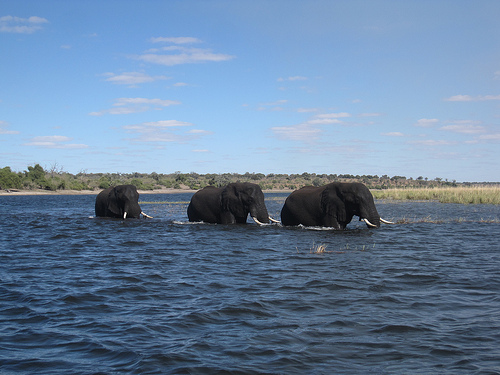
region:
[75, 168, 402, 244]
three elephants in the water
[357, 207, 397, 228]
elephant has two tusks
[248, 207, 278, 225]
elephant has two tusks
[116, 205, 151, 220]
elephant has two tusks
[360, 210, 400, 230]
tusks are color white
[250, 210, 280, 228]
tusks are color white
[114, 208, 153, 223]
tusks are color white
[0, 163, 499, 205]
trees behind the body of water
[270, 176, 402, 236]
the elephant is big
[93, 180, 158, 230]
the elephant is small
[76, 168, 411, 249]
elephants walking through the calm water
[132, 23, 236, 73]
thin white clouds in the blue sky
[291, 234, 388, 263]
grass sticking out of the blue lake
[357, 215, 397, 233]
long white tusks on the elephant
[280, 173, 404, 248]
elephant at the front of the line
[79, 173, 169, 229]
elephant at the back of the line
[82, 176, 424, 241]
elephants travelling through water in a line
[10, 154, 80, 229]
calm water near the shore where the plants are growing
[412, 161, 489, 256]
tall grass growing out of the water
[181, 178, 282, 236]
elephant walking in between two others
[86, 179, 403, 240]
Elephants crossing a river.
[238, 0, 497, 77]
A cloudless blue sky.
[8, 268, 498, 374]
A blue body of water.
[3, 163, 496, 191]
A wooded area beyond the river.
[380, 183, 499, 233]
Grass growing in the river.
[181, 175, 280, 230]
A black elephant with white tusks.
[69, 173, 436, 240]
The water is shallow where the elephants are crossing.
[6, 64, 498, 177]
Blue sky with clouds.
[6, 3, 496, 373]
A hot sunny day.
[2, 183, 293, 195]
A beach area by the river.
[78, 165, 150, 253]
this is a elephant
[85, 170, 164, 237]
the elephant is grey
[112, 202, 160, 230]
the elephant has tusk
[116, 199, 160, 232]
the tusks are white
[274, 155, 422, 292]
elephant is in water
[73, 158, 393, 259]
three elephants in a row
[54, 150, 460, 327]
three elephants in the water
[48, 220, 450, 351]
the water is brown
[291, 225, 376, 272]
weeds coming out of the water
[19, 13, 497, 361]
a bright and clear day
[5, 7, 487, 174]
a mostly clear blue sky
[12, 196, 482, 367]
a flat patch of water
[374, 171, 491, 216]
a flat patch of green grass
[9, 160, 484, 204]
a river bank with bushes growing on it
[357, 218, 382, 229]
an elephant's left tusk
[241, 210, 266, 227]
an elephant's left tusk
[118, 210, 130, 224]
an elephant's left tusk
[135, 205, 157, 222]
an elephant's right tusk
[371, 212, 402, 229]
an elephant's right tusk